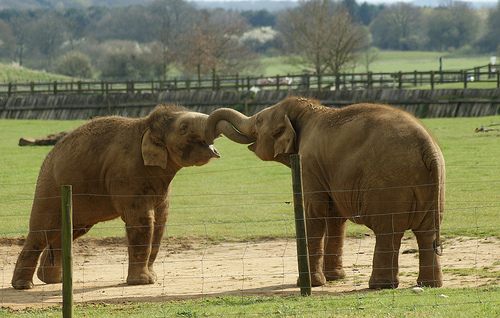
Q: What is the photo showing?
A: It is showing a pen.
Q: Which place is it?
A: It is a pen.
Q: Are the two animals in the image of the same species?
A: Yes, all the animals are elephants.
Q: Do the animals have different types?
A: No, all the animals are elephants.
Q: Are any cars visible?
A: No, there are no cars.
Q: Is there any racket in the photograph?
A: No, there are no rackets.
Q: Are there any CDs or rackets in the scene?
A: No, there are no rackets or cds.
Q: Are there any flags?
A: No, there are no flags.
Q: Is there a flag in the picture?
A: No, there are no flags.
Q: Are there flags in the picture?
A: No, there are no flags.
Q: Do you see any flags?
A: No, there are no flags.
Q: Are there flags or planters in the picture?
A: No, there are no flags or planters.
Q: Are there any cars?
A: No, there are no cars.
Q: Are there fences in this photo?
A: Yes, there is a fence.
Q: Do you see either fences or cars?
A: Yes, there is a fence.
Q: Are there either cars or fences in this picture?
A: Yes, there is a fence.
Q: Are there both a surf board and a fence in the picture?
A: No, there is a fence but no surfboards.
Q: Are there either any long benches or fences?
A: Yes, there is a long fence.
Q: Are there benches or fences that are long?
A: Yes, the fence is long.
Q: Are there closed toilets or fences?
A: Yes, there is a closed fence.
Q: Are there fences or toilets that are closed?
A: Yes, the fence is closed.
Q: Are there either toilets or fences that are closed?
A: Yes, the fence is closed.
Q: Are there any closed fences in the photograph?
A: Yes, there is a closed fence.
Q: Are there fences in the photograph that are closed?
A: Yes, there is a fence that is closed.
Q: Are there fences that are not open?
A: Yes, there is an closed fence.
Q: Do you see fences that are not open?
A: Yes, there is an closed fence.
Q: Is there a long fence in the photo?
A: Yes, there is a long fence.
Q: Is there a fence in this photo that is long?
A: Yes, there is a fence that is long.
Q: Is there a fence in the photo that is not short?
A: Yes, there is a long fence.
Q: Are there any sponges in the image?
A: No, there are no sponges.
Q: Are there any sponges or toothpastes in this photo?
A: No, there are no sponges or toothpastes.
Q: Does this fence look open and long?
A: No, the fence is long but closed.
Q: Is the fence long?
A: Yes, the fence is long.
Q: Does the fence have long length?
A: Yes, the fence is long.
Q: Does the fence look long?
A: Yes, the fence is long.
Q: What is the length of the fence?
A: The fence is long.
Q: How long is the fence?
A: The fence is long.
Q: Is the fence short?
A: No, the fence is long.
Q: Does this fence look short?
A: No, the fence is long.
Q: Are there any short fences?
A: No, there is a fence but it is long.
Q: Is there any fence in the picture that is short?
A: No, there is a fence but it is long.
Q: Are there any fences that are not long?
A: No, there is a fence but it is long.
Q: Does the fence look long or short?
A: The fence is long.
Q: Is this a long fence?
A: Yes, this is a long fence.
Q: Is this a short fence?
A: No, this is a long fence.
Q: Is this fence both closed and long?
A: Yes, the fence is closed and long.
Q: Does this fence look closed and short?
A: No, the fence is closed but long.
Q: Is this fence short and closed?
A: No, the fence is closed but long.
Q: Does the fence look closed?
A: Yes, the fence is closed.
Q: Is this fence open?
A: No, the fence is closed.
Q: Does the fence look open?
A: No, the fence is closed.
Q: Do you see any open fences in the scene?
A: No, there is a fence but it is closed.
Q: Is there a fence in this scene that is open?
A: No, there is a fence but it is closed.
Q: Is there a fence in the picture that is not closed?
A: No, there is a fence but it is closed.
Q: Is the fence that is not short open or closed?
A: The fence is closed.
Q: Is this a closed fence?
A: Yes, this is a closed fence.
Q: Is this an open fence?
A: No, this is a closed fence.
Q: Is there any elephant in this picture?
A: Yes, there is an elephant.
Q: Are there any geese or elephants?
A: Yes, there is an elephant.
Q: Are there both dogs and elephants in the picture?
A: No, there is an elephant but no dogs.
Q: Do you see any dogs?
A: No, there are no dogs.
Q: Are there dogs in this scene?
A: No, there are no dogs.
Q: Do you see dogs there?
A: No, there are no dogs.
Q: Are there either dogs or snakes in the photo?
A: No, there are no dogs or snakes.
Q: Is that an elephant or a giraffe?
A: That is an elephant.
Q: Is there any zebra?
A: No, there are no zebras.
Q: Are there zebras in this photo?
A: No, there are no zebras.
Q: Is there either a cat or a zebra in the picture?
A: No, there are no zebras or cats.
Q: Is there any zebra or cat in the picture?
A: No, there are no zebras or cats.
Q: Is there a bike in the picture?
A: No, there are no bikes.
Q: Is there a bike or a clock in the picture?
A: No, there are no bikes or clocks.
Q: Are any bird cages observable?
A: No, there are no bird cages.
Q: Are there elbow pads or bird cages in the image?
A: No, there are no bird cages or elbow pads.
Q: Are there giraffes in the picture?
A: No, there are no giraffes.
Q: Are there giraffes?
A: No, there are no giraffes.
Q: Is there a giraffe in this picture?
A: No, there are no giraffes.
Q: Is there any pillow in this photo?
A: No, there are no pillows.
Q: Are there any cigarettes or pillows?
A: No, there are no pillows or cigarettes.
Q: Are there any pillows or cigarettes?
A: No, there are no pillows or cigarettes.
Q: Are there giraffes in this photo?
A: No, there are no giraffes.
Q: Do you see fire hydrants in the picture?
A: No, there are no fire hydrants.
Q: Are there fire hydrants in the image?
A: No, there are no fire hydrants.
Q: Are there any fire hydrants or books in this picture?
A: No, there are no fire hydrants or books.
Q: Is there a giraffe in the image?
A: No, there are no giraffes.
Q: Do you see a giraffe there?
A: No, there are no giraffes.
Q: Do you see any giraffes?
A: No, there are no giraffes.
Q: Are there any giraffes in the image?
A: No, there are no giraffes.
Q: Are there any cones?
A: No, there are no cones.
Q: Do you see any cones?
A: No, there are no cones.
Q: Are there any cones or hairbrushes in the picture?
A: No, there are no cones or hairbrushes.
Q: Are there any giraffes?
A: No, there are no giraffes.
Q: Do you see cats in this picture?
A: No, there are no cats.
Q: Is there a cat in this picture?
A: No, there are no cats.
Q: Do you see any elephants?
A: Yes, there is an elephant.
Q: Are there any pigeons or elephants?
A: Yes, there is an elephant.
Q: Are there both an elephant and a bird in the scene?
A: No, there is an elephant but no birds.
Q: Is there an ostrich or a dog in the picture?
A: No, there are no dogs or ostriches.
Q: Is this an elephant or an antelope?
A: This is an elephant.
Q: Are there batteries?
A: No, there are no batteries.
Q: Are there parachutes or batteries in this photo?
A: No, there are no batteries or parachutes.